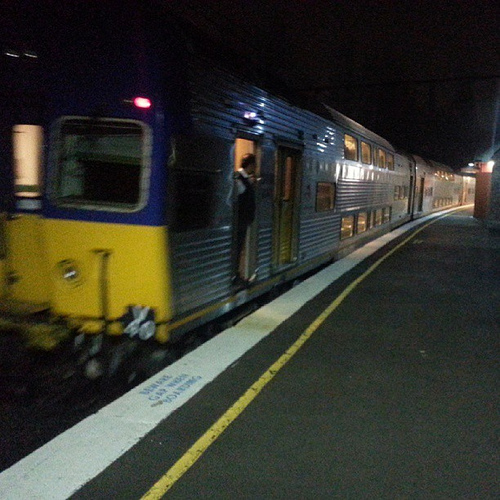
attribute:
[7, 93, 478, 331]
train — blue, yellow, silver, moving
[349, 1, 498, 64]
sky — black, dark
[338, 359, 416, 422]
ground — dark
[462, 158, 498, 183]
lights — on